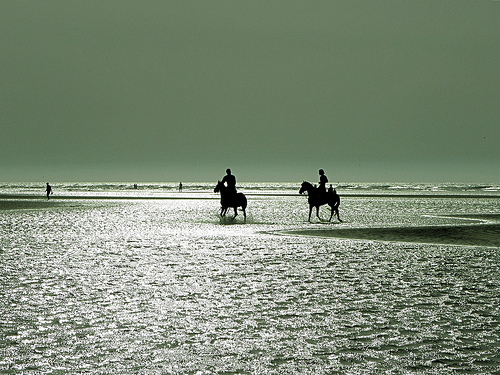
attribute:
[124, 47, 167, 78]
sky — clear, blue